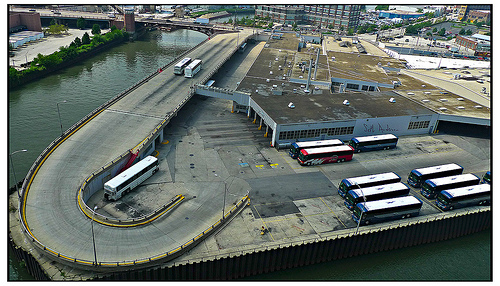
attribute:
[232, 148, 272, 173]
grates — yellow, blue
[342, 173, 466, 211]
buses — parked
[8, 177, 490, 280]
fence — dark brown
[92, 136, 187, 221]
bus — white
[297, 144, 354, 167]
bus — red, white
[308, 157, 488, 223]
buses — blue, white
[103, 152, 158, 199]
bus — white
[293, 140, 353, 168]
bus — red